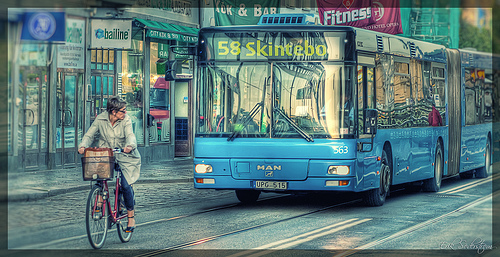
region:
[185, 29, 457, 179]
The bus is blue.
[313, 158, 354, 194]
The light is on.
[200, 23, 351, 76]
The lettering is yellow.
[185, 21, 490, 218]
The bus is moving.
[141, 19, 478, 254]
The bus is on the road.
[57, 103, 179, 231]
The woman is on a bike.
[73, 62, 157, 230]
The has a tan jacket.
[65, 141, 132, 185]
The basket is tan.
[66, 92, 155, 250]
Her bike is red.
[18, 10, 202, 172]
The shops are along the street.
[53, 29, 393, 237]
woman on bike crossing in front of bus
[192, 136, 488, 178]
bottom half of bus is blue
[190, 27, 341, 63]
number and destination on top front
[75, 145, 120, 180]
woman has a bag in the bike basket in front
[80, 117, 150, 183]
woman wearing tan coat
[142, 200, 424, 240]
street looks wet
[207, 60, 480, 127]
buildings are reflected in the bus windshield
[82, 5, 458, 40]
signs on the storefronts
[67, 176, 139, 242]
woman riding red bike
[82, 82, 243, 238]
woman on bike looking at bus behind her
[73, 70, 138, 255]
a woman riding a bike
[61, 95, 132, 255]
a woman riding a red bike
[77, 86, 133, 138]
a woman wearing glasses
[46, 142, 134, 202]
a bike with a basket on the handle bars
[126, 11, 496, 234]
a blue public transportation bus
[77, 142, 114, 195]
a brown paper bag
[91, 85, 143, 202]
a woman wearing a brown trench coat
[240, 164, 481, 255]
lines painted on a roadway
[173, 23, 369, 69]
yellow letters and numbers on a bus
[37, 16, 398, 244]
a woman on a bike in a roadway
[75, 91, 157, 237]
The woman is riding her bike.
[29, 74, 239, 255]
The woman is on the tracks.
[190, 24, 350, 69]
The words are yellow.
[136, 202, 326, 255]
The tracks are on the ground.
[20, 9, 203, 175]
The shops are along the side.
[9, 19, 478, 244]
The city is busy.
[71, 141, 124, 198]
The basket is brown.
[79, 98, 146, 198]
Her jacket is tan.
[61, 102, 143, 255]
The bike is red.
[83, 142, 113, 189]
bag on front of bike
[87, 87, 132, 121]
woman wearing glasses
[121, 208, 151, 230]
woman wearing high heals on bike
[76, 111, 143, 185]
woman wearing tan jacket on bike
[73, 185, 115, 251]
front of red bike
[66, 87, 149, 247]
a woman riding a red bike in the road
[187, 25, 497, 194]
a blue bus number 58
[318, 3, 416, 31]
a red Fitness advertising sign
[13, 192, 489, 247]
a wet street bike and bus is on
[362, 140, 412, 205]
a black tire on a blue bus